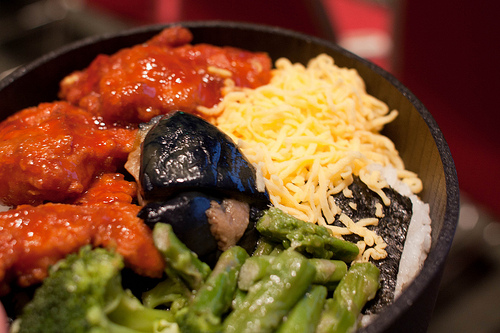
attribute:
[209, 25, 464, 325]
rim — black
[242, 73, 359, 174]
rice — white, cooked, sticky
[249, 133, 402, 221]
grated cheese — yellow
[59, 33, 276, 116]
sauce — red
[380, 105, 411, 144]
ground — chopped, green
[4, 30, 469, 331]
food — reddish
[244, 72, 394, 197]
cheese — grated, yellow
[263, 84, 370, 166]
cheese — yellow, grated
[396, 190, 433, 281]
rice — white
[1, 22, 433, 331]
meal — complete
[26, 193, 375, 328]
vegetables — green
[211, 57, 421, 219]
cheddar cheese — sprinkled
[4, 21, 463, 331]
dish — shredded, black, deep, wooden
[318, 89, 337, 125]
rice — white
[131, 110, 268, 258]
food — black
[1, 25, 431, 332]
food — cooked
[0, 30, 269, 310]
food — orange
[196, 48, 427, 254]
cheese — orange, yellow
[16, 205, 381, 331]
asparagus — cooked